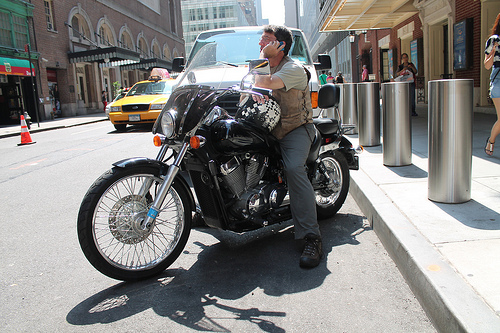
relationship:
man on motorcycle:
[248, 26, 308, 108] [146, 88, 275, 235]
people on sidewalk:
[352, 48, 429, 125] [322, 98, 498, 328]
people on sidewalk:
[322, 40, 499, 93] [344, 107, 493, 332]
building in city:
[27, 1, 186, 120] [2, 2, 497, 332]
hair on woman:
[484, 10, 499, 43] [481, 10, 499, 157]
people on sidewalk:
[396, 52, 420, 116] [406, 109, 439, 156]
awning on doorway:
[67, 40, 142, 67] [81, 57, 101, 102]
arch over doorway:
[69, 10, 100, 110] [73, 62, 100, 107]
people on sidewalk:
[317, 0, 499, 160] [302, 94, 499, 328]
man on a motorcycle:
[249, 23, 326, 270] [91, 96, 318, 278]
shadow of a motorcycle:
[65, 210, 373, 331] [76, 34, 358, 281]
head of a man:
[256, 21, 295, 68] [233, 17, 332, 275]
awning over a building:
[67, 40, 142, 67] [3, 2, 188, 110]